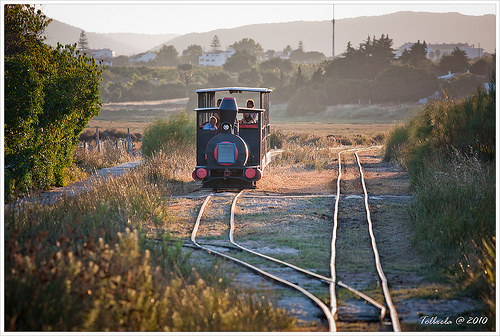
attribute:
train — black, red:
[195, 76, 300, 208]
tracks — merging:
[302, 147, 402, 330]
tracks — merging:
[182, 197, 343, 309]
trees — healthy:
[104, 33, 487, 115]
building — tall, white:
[195, 46, 235, 70]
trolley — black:
[173, 72, 280, 183]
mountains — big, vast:
[41, 12, 491, 51]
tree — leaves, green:
[24, 39, 105, 197]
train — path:
[163, 76, 280, 188]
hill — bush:
[294, 58, 498, 132]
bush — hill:
[384, 102, 497, 247]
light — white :
[219, 122, 231, 132]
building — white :
[397, 36, 488, 68]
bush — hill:
[381, 117, 412, 161]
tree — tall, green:
[6, 7, 61, 189]